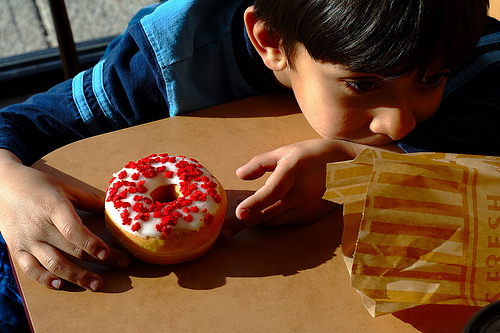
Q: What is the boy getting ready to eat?
A: Doughnut.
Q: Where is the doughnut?
A: On the table.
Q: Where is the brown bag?
A: Table.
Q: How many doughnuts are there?
A: One.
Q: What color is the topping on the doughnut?
A: Red.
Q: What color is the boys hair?
A: Black.